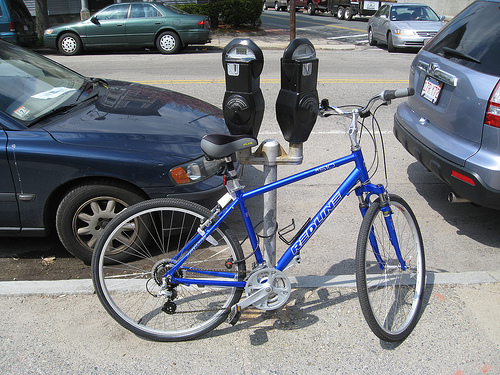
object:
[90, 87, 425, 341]
bicycle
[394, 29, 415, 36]
headlight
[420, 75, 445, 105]
tag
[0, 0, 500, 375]
ground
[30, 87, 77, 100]
paper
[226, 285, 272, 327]
foot peddles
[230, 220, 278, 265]
chain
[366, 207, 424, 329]
spokes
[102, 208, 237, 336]
spokes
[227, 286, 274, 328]
pedal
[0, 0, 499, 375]
road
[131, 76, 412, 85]
paint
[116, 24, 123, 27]
handle door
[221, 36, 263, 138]
parking meter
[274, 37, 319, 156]
meter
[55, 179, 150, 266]
tire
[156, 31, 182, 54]
tire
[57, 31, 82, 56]
tire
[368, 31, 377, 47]
tire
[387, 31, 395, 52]
tire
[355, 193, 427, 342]
tire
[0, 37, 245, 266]
car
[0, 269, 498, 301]
curb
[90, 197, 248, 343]
tire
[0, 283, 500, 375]
gravel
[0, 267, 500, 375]
sidewalk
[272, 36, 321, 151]
parking meter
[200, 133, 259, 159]
seat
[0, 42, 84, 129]
windshield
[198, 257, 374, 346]
shadow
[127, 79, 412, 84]
lines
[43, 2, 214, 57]
car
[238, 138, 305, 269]
post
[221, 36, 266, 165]
meter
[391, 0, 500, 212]
car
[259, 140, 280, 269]
pole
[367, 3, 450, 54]
car